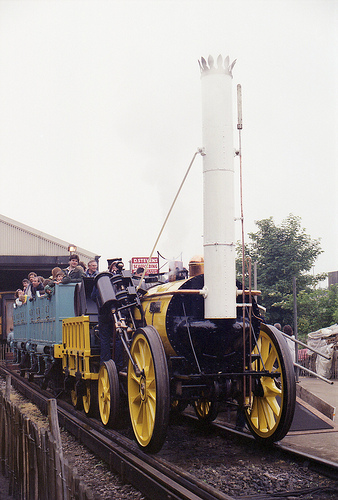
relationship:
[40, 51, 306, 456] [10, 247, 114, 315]
engine pulling passengers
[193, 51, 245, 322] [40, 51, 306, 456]
stack on engine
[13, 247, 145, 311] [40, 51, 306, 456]
people in engine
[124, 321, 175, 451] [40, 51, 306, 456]
wheel on engine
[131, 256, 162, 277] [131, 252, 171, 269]
signage shaped like arrow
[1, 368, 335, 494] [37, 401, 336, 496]
tracks filled with gravel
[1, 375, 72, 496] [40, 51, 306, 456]
fence beside engine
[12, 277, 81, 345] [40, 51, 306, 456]
bucket connected to engine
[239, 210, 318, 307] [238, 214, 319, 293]
tree with leaves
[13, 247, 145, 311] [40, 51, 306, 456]
people riding engine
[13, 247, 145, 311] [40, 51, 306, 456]
people on engine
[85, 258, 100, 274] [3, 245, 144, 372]
person in car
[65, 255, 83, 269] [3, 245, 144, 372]
person in car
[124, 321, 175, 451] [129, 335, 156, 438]
wheel has interior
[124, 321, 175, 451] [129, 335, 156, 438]
wheel with interior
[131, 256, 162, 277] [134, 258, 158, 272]
advertisement for something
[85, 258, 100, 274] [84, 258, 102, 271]
person has head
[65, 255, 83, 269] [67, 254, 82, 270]
person has head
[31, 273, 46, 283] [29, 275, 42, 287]
person has head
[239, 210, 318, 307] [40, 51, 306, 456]
tree next to engine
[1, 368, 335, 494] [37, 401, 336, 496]
railroad with gravel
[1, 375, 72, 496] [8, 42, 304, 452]
fence next to train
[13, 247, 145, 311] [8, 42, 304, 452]
people in train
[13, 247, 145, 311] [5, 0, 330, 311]
people in open air